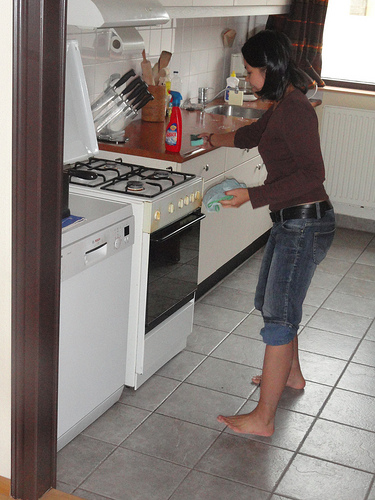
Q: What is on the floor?
A: Tile.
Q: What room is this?
A: Kitchen.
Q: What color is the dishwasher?
A: White.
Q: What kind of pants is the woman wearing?
A: Jeans.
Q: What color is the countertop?
A: Red.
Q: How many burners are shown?
A: Four.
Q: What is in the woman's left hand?
A: A rag.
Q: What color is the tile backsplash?
A: White.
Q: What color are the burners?
A: Black.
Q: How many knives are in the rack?
A: 5.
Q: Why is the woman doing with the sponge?
A: Cleaning the kitchen counter.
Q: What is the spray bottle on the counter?
A: Cleansing agent.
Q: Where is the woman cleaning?
A: Kitchen.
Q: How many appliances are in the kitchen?
A: 3.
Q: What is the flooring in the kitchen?
A: Tiles.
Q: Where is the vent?
A: On the wall under the window.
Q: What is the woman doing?
A: Cleaning.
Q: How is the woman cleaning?
A: With a sponge.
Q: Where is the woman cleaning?
A: In the kitchen.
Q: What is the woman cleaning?
A: The countertop.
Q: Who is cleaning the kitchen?
A: A woman.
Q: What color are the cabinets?
A: White.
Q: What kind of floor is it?
A: Tile.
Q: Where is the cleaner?
A: On the counter.